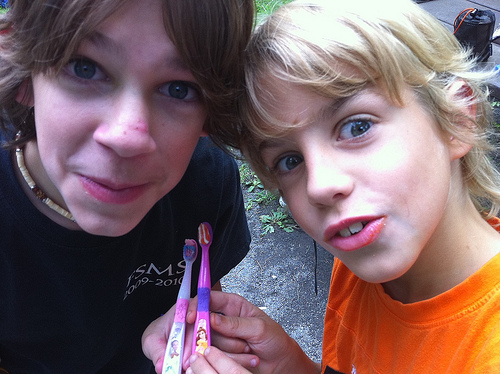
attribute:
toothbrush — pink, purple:
[193, 215, 220, 360]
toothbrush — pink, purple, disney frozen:
[159, 232, 197, 373]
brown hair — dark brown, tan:
[4, 0, 260, 173]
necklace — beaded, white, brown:
[6, 127, 78, 225]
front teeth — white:
[336, 217, 371, 241]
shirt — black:
[0, 136, 250, 374]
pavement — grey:
[233, 169, 329, 355]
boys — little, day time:
[1, 3, 497, 374]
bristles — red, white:
[194, 217, 215, 251]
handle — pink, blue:
[161, 269, 193, 373]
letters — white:
[121, 255, 199, 299]